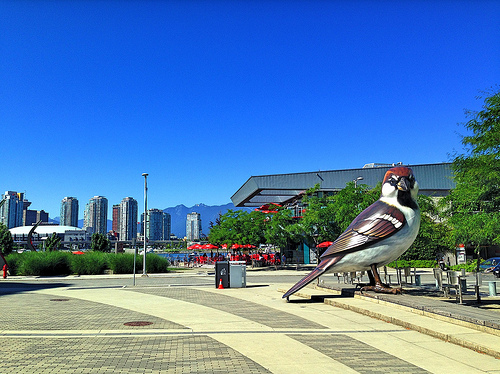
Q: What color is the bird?
A: Brown and white.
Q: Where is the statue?
A: Park.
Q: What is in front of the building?
A: Trees.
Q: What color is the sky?
A: Blue.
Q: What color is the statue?
A: Brown and white.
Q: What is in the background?
A: City.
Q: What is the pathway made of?
A: Stone.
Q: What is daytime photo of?
A: Outdoor scene with summer features.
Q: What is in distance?
A: City skyline and high towers.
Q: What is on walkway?
A: Cream stripes on cobbled surface.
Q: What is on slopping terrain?
A: Line arcs.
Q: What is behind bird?
A: Roof and greenery.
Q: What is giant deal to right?
A: Bird statue.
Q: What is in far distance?
A: Tall buildings.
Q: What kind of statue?
A: Large bird.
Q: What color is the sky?
A: Blue.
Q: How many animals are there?
A: One.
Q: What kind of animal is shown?
A: Bird.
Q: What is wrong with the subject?
A: Bird too large.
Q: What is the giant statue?
A: Bird.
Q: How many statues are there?
A: One.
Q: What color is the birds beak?
A: Black.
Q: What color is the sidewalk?
A: Tan.